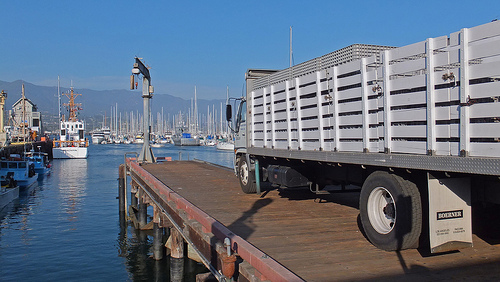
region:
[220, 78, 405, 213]
truck parked on a pier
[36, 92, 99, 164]
boat sitting in a bay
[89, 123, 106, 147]
yachts in the water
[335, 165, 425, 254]
rear tire on a truck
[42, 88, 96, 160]
docked fishing boat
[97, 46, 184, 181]
crane for loading cargo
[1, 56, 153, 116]
distant mountain range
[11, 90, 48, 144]
building near the water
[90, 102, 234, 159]
group of docked boats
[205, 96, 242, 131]
a truck's rearview mirror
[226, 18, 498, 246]
A large grey truck for hauling stuff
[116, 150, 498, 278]
A pier for trucks to park on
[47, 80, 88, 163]
A large white fishing boat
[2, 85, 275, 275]
Calm ocean water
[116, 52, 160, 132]
An orange pulley for the boats to use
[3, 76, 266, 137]
Mountains back in the distance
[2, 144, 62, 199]
Personal boats docked at the side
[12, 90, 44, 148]
A two story grey building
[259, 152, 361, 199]
A large black gas tank for the grey truck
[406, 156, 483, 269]
Grey mud flap for the truck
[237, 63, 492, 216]
this is a lorry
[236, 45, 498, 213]
the lorry is grey in color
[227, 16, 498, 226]
the lorry is long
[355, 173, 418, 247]
the lorry has black tyre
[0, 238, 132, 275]
water is beneath the bridge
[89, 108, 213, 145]
these are ships on the sea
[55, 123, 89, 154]
the ship is white in color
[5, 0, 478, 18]
the sky is blue in color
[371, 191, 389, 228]
the wheel has white rims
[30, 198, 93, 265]
the water is calm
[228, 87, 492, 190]
Large gray hauling truck on dock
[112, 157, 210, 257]
Rusty metal beams under pier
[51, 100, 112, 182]
Whit boat in bay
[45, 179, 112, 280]
Calm bay water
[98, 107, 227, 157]
Boats docked within the bay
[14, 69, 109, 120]
Mountainous area behind bay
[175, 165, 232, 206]
Wooden pier planks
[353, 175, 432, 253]
Large black truck tires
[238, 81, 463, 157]
Wooden gray paneling along hauling truck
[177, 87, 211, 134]
Sails of sail boats in bay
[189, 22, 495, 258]
large truck parked on steel and concrete dock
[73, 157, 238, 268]
steel and concrete boat dock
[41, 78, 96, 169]
white fishing boat tied to pier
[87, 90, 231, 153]
many fishing boats or pleasure crafts docked in the distance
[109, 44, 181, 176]
pneumatic crane for lifting heavy things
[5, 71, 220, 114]
mountains are in the distant background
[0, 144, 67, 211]
smaller boats are docked in the shade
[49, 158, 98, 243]
reflection of boat in the water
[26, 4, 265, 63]
clear blue sky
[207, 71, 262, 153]
side view mirror of truck parked near end of dock